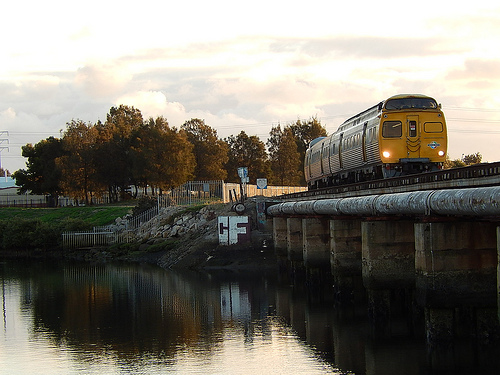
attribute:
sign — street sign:
[256, 178, 268, 189]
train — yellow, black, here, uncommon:
[304, 93, 448, 189]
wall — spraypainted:
[170, 202, 272, 272]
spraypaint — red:
[222, 184, 309, 201]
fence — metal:
[61, 178, 224, 250]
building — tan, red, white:
[2, 174, 24, 197]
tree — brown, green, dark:
[52, 119, 99, 206]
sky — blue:
[1, 0, 499, 175]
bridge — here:
[268, 162, 499, 298]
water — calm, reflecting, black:
[0, 255, 498, 374]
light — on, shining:
[385, 152, 391, 159]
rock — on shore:
[176, 218, 184, 225]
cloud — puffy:
[115, 90, 256, 141]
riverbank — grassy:
[0, 206, 127, 249]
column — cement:
[414, 222, 496, 310]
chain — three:
[406, 134, 420, 155]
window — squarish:
[385, 120, 402, 135]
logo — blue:
[429, 141, 438, 149]